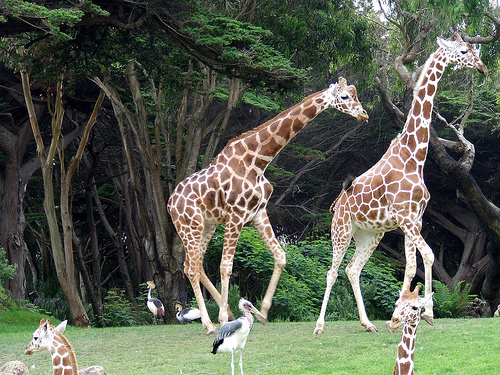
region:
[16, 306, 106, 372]
a little baby giraffe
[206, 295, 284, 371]
looks like a stork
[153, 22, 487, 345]
the grown giraffes are huge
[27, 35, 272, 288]
a nice thicket of trees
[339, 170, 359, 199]
a tick bird on his back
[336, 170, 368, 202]
the tick bird picks off bugs/parasites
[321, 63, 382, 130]
the giraffe has horns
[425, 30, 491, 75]
the head of a giraffe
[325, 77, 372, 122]
the head of a giraffe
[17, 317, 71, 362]
the head of a giraffe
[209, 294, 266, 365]
a black and white pelican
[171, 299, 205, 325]
a black and white duck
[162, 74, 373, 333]
a tall giraffe walking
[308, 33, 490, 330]
a tall giraffe walking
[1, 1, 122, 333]
a tall savannah tree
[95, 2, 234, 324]
a tall savannah tree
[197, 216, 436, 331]
a large green bush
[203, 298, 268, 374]
A bird on the grass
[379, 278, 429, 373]
A young giraffe on the grass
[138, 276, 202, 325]
Birds in front of a tree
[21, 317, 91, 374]
A small giraffe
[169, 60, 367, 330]
A large giraffe on the grass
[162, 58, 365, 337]
A tall giraffe in front of trees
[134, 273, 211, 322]
Two birds behind giraffe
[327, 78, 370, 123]
The face of a giraffe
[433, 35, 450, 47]
The ear of a giraffe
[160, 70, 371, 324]
this is a giraffe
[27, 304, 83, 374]
this is a giraffe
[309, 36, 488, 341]
this is a giraffe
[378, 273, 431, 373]
this is a giraffe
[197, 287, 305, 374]
this is a bird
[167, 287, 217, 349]
this is a bird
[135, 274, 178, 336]
this is a bird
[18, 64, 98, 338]
this is a bark of a tree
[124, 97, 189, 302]
this is a bark of a tree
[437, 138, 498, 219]
this is a bark of a tree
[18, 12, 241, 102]
Green trees near a giraffe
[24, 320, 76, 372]
A head of a giraffe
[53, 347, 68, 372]
Light brown and white colored neck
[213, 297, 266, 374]
A seagull near a giraffe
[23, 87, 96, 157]
Limbs of a tree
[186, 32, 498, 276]
Two giraffes walking together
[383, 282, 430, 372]
Head of a giraffe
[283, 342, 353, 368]
Green grass giraffes are walking on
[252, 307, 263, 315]
Peak of a bird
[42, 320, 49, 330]
Ear of a giraffe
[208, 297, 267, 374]
pelican in front of giraffe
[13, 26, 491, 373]
a group of animals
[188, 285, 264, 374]
bird on the ground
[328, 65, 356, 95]
ossicones on the giraffe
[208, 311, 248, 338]
black wing on bird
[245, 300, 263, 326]
beak of the bird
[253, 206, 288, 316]
giraffe leg is bent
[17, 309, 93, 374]
a young giraffe baby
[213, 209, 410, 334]
bush in the background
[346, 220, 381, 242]
white underbelly of giraffe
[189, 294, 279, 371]
white and black bird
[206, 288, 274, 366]
white and black bird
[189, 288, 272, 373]
white and black bird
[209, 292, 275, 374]
white and black bird